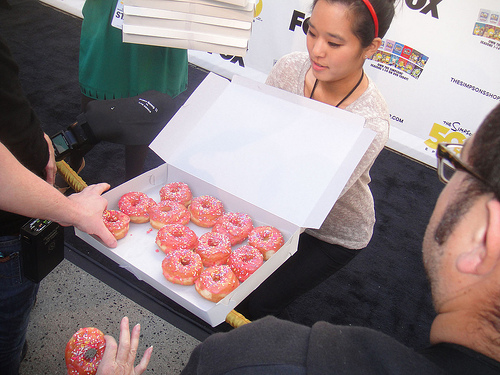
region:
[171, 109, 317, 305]
white cardboard box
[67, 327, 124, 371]
woman holding pink donut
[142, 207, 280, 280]
a box full of donuts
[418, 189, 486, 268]
a mans thick side burn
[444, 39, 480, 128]
a background banner for advertisement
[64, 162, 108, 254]
a man grabbing a donut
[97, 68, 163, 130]
a black and white shirt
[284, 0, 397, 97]
a woman looking down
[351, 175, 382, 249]
a white see through long sleeve shirt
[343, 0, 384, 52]
red headband on woman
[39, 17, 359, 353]
hand reaches for a donut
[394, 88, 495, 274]
this man has sideburns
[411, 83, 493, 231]
this man has dark hair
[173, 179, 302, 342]
the donuts are pink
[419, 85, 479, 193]
this is a simpsons event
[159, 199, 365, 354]
donuts have white sprinkles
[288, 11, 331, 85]
the girl is asian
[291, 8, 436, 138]
she has a red headband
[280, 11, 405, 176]
her shirt is white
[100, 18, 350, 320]
the box is open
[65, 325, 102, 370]
a pink frosted doughnut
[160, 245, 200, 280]
a pink frosted doughnut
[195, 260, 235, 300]
a pink frosted doughnut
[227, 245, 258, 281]
a pink frosted doughnut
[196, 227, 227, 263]
a pink frosted doughnut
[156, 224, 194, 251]
a pink frosted doughnut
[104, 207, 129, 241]
a pink frosted doughnut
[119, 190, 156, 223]
a pink frosted doughnut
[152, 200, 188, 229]
a pink frosted doughnut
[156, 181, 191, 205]
a pink frosted doughnut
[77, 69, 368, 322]
donuts in open box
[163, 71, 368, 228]
inside of box cover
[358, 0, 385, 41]
red band in hair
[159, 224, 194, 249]
pink frosting on donut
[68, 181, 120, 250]
fingers grabbing donut with sprinkles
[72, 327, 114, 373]
top of donut in index finger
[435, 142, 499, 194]
glasses on man's head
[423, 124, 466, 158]
yellow numbers on wall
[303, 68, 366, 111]
black cord on neck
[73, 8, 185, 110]
green dress on body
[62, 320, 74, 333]
floor made of marble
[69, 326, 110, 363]
doughnut being held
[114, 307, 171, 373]
3 fingers are shown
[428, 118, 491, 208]
man has glasses on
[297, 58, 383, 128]
black string around the neck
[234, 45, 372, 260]
woman holding box of doughnuts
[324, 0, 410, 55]
red headband in hair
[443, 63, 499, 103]
the simpsons shop written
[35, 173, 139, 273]
hand getting a doughnut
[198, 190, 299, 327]
6 doughnuts are shown